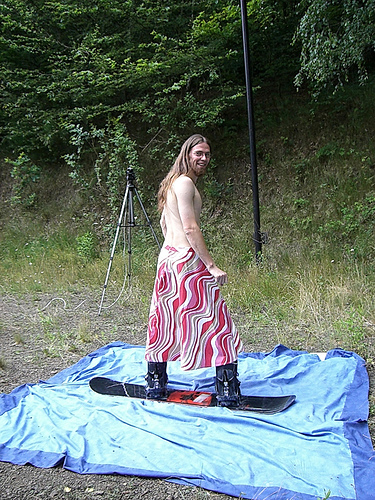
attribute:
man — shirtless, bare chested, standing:
[146, 133, 242, 406]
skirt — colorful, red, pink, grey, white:
[149, 242, 243, 368]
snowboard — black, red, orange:
[89, 374, 296, 414]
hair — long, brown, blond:
[159, 130, 209, 212]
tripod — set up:
[94, 187, 171, 323]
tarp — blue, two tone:
[6, 335, 374, 498]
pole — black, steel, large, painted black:
[237, 2, 267, 267]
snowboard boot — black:
[144, 361, 170, 397]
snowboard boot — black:
[215, 361, 242, 409]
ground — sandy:
[3, 262, 373, 499]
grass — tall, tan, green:
[3, 229, 369, 341]